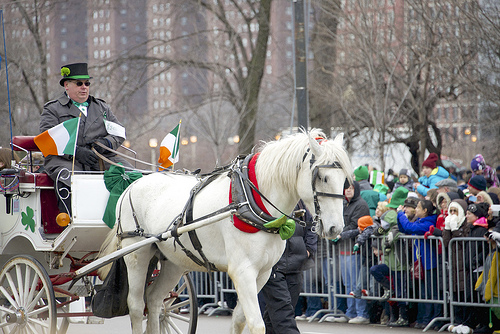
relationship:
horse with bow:
[87, 90, 358, 332] [266, 215, 296, 240]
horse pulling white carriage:
[91, 125, 357, 331] [0, 169, 199, 332]